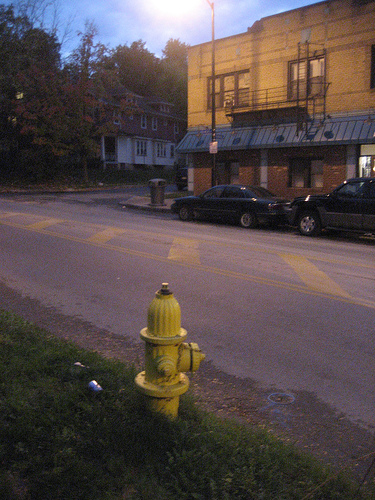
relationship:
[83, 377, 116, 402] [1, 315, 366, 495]
can on ground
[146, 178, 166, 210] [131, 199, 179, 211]
can on sidewalk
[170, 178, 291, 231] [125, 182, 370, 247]
car parked on side of street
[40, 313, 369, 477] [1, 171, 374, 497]
leaves on ground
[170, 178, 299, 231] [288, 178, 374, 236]
car is parked in front of car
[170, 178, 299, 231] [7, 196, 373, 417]
car on road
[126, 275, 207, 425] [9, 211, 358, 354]
hydrant on street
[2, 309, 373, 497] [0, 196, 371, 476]
grass on side of road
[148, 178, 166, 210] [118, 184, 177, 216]
can on sidewalk